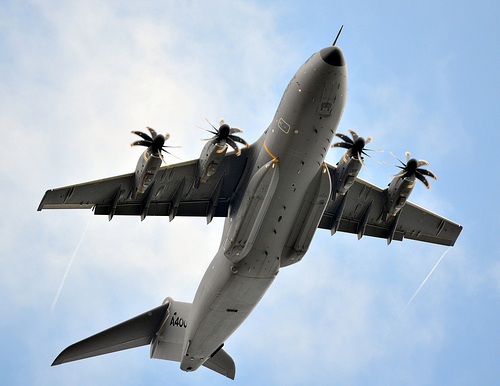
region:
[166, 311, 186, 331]
LETERS AND NUMBERS ON AIRPLANE TAIL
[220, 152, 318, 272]
CLOSED AIRPLANE LANDING GEARS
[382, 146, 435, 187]
MOVING AIRPLANE PROPELLER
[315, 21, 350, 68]
BLACK NOSE CONE OF AIRPLANE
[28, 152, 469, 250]
WING SECTIONS OF GREY AIRPLANE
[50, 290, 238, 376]
TAIL WINGS OF AIRPLANE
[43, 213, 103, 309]
JET STREAM OF AIRPLANE MOTOR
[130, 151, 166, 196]
SINGLE MOTOR OF AN AIRPLANE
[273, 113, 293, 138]
COCKPIT DOOR ON SIDE OF AIRPLANE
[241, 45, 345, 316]
MAIN BODY OF GREY AIRPLANE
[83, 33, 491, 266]
Four prop engines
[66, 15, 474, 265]
Orange highlights on plane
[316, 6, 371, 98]
Antenna on nose of plane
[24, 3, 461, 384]
High clouds in the sky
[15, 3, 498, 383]
Mixed sun and clouds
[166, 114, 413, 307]
Where the landing gear is stored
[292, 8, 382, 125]
Black tip on nose of plane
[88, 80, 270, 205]
Eight blades on each propeller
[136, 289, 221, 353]
The planes identification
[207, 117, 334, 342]
The landing gear is not out.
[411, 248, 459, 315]
A white strip of jetstream cloud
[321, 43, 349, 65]
Curved, dark nose of an airplane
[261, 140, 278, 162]
Orange stripe on an airplane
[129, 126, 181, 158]
A propeller on an airplane wing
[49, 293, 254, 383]
Airplane rudders on the back of the plane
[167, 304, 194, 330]
Black call numbers on the airplane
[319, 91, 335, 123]
Front landing wheel cover on a plane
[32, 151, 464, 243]
Both wings on a flying airplane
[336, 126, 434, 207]
Two propellers on the left wing of an airplane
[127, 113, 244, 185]
Two propellers on the right wing of an airplane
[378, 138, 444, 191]
the spinning propeller of an airplane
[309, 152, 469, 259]
the wing of an airplane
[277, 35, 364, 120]
the nose of an airplane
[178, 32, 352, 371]
the body of an airplane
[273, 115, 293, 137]
the door of an airplane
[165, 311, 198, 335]
A400 written in black lettering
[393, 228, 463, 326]
streams of moisture coming from the plane wing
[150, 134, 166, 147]
the spinner of a propeller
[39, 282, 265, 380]
the horizontal stabilizers of an airplane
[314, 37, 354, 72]
the radome of an airplane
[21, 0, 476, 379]
Military plane Hercules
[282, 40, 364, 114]
Cockpit of military plane Hercules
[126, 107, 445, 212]
Four engines of plane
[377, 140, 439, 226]
Black and yellow engine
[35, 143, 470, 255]
Wings of Hercules plane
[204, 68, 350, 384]
Fuselage of military plane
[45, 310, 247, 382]
Horizontal stabilizer of military plane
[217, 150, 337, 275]
System for landing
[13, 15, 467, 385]
Military plane flying in the air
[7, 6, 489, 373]
Blue sky with some clouds